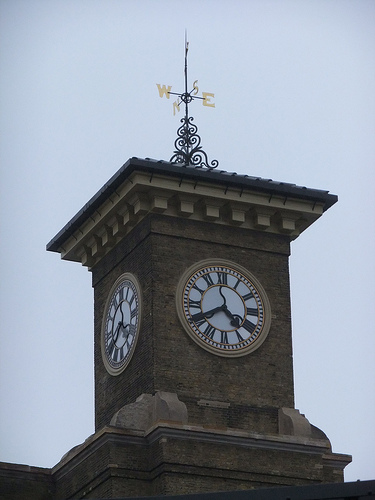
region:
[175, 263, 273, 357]
clock on top of building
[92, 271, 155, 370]
clock on top of building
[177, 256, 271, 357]
black and white clock on top of building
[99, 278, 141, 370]
black and white clock on top of building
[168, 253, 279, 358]
tan black and white clock on top of building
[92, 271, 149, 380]
tan black and white clock on top of building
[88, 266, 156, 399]
tan black and white clock with black hands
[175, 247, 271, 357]
tan black and white clock with black hands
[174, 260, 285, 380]
black and white clock with black hands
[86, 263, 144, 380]
black and white clock with black hands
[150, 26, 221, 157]
a weather vane on top of the building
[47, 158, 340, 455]
a short clocktower on top of the building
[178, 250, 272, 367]
a clock on the tower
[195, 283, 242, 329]
the hands of the clock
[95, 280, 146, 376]
another clock on the tower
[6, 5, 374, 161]
the blue sky above everything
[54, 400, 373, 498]
the area below the tower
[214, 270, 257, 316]
some numbers on the clock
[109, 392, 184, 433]
some decorative blocks on the building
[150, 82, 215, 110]
the letters on the weather vane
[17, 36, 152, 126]
a blue sky.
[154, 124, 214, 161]
a black metal stand.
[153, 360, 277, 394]
a brick tower building.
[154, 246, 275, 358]
a clock is on top of the building.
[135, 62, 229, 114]
a building has the letters w s n e.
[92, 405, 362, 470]
a ledge on the tower.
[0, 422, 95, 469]
a roof on top of the tower.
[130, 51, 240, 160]
the letters are for west north east and south.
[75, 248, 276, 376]
a tower with two clocks.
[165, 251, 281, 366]
the clock says 4:40.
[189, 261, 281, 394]
Clock has white face on it.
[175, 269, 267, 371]
Black hands on clock.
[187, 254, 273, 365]
Clock has black numbers on it.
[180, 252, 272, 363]
Numbers on clock are roman numeral.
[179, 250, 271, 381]
Clock is round in shape.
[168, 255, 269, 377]
Clock is in side of brick tower.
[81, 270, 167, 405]
Clock has white face.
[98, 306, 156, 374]
Clock has black hands.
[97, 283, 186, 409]
Clock has black numbers.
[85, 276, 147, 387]
Numbers on clock are roman numeral.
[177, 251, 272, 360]
Clock on tower of building.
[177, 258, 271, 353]
Black Roman numerals on clock.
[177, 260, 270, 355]
White background on clock face.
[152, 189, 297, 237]
Small decorative cement blocks on tower.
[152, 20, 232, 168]
Weather vein on top of tower.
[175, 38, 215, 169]
Black ornate metal on weather vein.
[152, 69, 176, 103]
Gold letter on weather vein.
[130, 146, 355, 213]
Black roof tiles on tower.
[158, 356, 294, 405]
Brown bricks make the tower.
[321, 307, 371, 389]
Gray sky in the background.